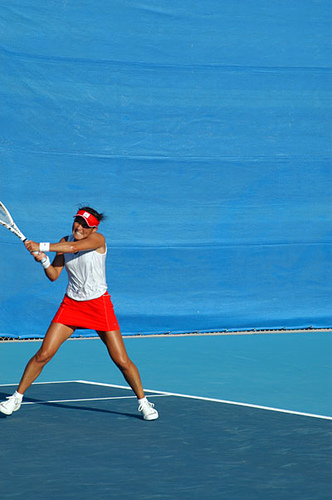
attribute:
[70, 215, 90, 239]
face — with dimples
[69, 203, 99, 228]
visor — red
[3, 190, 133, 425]
tennis player — female 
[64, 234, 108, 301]
blouse — white 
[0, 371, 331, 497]
tennis court — blue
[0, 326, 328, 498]
field — part of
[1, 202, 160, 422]
female player — female 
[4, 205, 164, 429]
woman — white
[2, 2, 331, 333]
wall — blue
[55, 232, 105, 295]
shirt — white, sleeveless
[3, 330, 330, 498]
tennis court — blue 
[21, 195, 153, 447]
woman — tennis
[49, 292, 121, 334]
skirt — red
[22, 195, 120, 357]
player — is female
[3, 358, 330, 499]
tennis court — green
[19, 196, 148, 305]
tennis player — female 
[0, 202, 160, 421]
player — female 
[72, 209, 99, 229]
cap — red 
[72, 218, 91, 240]
face — intense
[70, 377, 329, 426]
lines — white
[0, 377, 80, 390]
lines — white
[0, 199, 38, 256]
racket — tennis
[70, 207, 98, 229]
hat — red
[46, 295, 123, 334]
skirt — red 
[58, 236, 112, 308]
shirt — white 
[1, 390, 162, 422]
sneakers — white 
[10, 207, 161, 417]
tennis player — female 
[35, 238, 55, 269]
armbands — white